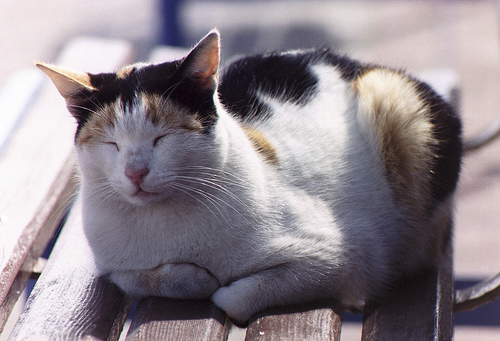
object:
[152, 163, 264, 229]
cat's whiskers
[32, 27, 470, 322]
cat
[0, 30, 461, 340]
bench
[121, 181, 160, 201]
mouth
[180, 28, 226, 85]
ear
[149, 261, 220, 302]
paw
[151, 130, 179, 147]
eye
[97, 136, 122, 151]
eye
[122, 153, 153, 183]
nose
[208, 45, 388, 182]
back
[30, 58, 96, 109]
ear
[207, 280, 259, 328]
paw